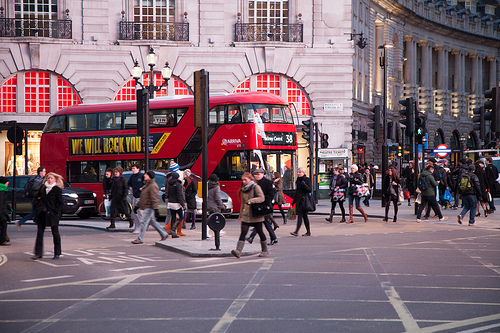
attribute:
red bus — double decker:
[16, 88, 333, 242]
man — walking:
[418, 164, 446, 222]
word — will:
[83, 140, 108, 155]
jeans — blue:
[131, 209, 168, 245]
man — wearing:
[131, 163, 167, 243]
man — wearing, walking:
[130, 169, 170, 244]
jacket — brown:
[131, 179, 162, 209]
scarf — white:
[220, 169, 277, 199]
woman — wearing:
[196, 130, 291, 250]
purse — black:
[247, 200, 272, 216]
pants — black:
[26, 205, 77, 273]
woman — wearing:
[29, 170, 71, 264]